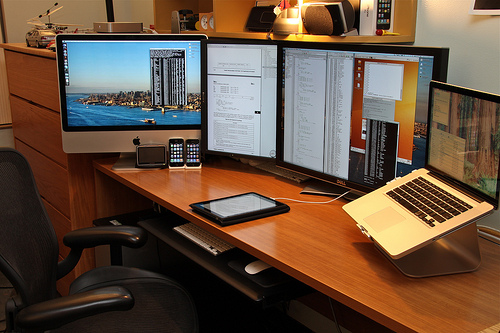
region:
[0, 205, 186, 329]
this is an office chair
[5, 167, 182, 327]
the office chair is black in color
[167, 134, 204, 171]
these are phones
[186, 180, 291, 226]
this is a tablet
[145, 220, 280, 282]
this is a keyboard of a computer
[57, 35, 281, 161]
these are desktops of a compters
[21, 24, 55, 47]
this is a toy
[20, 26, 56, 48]
the toy is silver in color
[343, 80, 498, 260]
this is a laptop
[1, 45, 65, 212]
these are office draws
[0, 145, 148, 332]
Black computer chair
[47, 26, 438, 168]
Three computer monitors on a desk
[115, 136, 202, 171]
Three smartphones on a desk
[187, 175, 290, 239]
Tablet laying on a desk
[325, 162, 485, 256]
Large keyboard mounted on a desk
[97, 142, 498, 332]
Wood colored desk in a room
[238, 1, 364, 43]
Two speakers on a shelf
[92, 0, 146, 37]
Lamp on a dresser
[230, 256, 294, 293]
Mouse on a drawer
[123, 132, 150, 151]
An apple monitor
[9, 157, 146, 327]
this is a chair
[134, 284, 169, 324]
the chair is black in color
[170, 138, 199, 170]
these are two mobile phones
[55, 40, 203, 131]
this is a computer monitor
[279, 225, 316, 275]
this is a table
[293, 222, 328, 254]
the table is wooden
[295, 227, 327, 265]
the table is brown in color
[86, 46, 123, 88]
the monitor is on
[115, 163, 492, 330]
a large wooden desk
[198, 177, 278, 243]
tablet on desk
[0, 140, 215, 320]
black office chair near desk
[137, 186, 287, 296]
keyboard on pull-out shelf attached to desk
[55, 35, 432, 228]
three large computer monitors on desk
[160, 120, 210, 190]
two smart phones on desk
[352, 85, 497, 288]
laptop computer on stand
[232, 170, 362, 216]
white cord connecting tablet to monitor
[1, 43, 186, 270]
wooden file cabinet next to desk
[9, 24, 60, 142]
toy car on top of file cabinet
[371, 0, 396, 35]
iPhone box on a shelf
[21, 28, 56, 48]
Model car on filing cabinet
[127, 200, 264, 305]
Keyboard tray under the desk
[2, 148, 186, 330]
Black mesh office chair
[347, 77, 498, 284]
Laptop mounted on a stand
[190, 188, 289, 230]
Tablet charging on the desk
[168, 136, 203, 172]
Two iPhones in charging stand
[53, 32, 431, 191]
Three computer monitors on the desk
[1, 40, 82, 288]
Filing cabinet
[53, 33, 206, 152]
Apple monitor